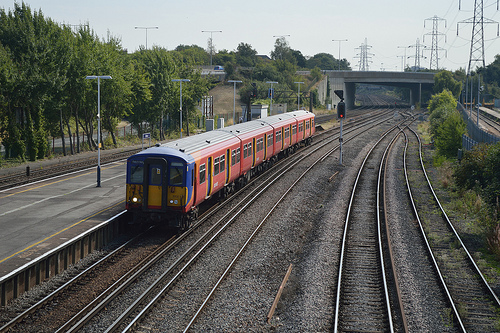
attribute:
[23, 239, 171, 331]
track — railway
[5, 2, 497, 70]
sky — blue 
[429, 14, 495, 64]
clouds — white 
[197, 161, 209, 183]
window — glass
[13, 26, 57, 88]
leaves — green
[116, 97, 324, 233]
train — red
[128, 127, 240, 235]
railcar — blue, yellow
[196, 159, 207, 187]
window — glass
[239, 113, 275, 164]
train — red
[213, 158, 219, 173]
window — glass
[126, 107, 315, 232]
railcar — red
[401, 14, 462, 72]
wire towers — electrical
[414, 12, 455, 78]
tower — electrical, metal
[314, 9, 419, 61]
clouds — white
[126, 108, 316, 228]
train — red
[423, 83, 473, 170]
bushes — green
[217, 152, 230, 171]
window — glass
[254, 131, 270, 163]
window — glass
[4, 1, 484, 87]
sky — blue